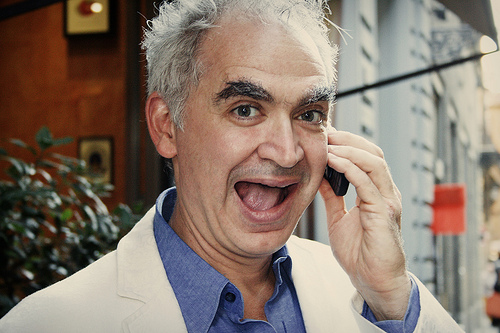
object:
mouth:
[230, 178, 304, 223]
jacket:
[0, 204, 466, 331]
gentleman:
[0, 0, 467, 333]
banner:
[431, 183, 466, 234]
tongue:
[240, 183, 286, 210]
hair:
[141, 0, 352, 131]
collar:
[153, 185, 294, 332]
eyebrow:
[211, 75, 274, 107]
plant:
[0, 122, 154, 319]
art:
[77, 138, 111, 200]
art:
[62, 0, 109, 37]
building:
[327, 0, 499, 332]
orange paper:
[432, 184, 466, 234]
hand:
[318, 126, 407, 296]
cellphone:
[323, 165, 349, 195]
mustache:
[226, 164, 307, 182]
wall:
[3, 3, 149, 229]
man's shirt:
[153, 187, 309, 333]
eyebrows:
[297, 82, 337, 108]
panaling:
[4, 2, 119, 278]